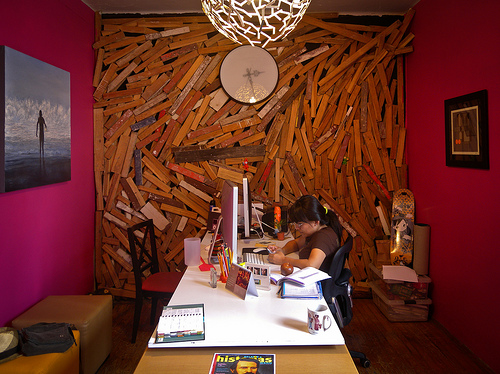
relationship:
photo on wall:
[2, 44, 74, 191] [2, 1, 98, 329]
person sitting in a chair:
[272, 197, 342, 281] [326, 238, 351, 325]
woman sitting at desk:
[271, 195, 345, 279] [135, 223, 357, 373]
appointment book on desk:
[155, 304, 205, 345] [135, 223, 357, 373]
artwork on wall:
[445, 88, 488, 168] [405, 1, 498, 366]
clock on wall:
[219, 45, 277, 104] [91, 14, 417, 298]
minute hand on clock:
[244, 69, 265, 75] [219, 45, 277, 104]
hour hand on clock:
[246, 71, 256, 94] [219, 45, 277, 104]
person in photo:
[36, 110, 48, 162] [2, 44, 74, 191]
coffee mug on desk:
[308, 304, 331, 334] [135, 223, 357, 373]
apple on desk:
[281, 261, 295, 277] [135, 223, 357, 373]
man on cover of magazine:
[233, 358, 258, 373] [209, 352, 278, 373]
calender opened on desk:
[224, 261, 260, 298] [135, 223, 357, 373]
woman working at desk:
[271, 195, 345, 279] [135, 223, 357, 373]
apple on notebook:
[281, 261, 295, 277] [273, 266, 330, 287]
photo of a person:
[2, 44, 74, 191] [36, 110, 48, 162]